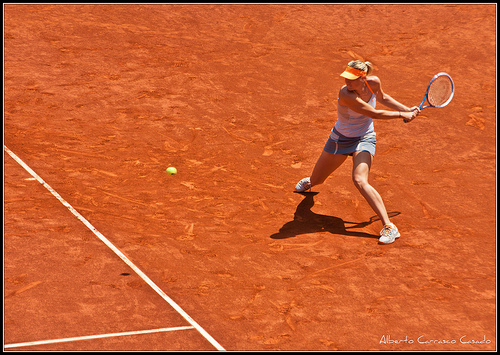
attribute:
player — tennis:
[293, 58, 421, 245]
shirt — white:
[331, 106, 417, 152]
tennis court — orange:
[4, 4, 499, 354]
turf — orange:
[8, 6, 495, 351]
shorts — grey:
[321, 127, 376, 157]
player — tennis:
[241, 39, 491, 263]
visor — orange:
[328, 63, 377, 91]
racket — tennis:
[403, 69, 456, 122]